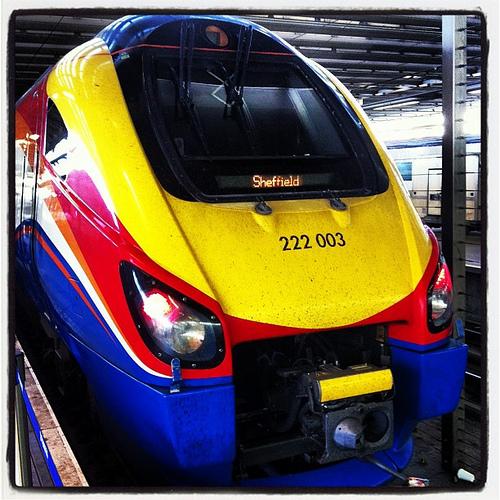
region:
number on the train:
[266, 228, 355, 266]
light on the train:
[143, 315, 208, 369]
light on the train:
[412, 270, 462, 352]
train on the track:
[97, 162, 458, 481]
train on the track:
[8, 22, 430, 421]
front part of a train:
[46, 30, 496, 491]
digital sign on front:
[205, 175, 347, 195]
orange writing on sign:
[240, 167, 310, 191]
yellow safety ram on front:
[300, 370, 402, 468]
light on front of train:
[110, 263, 220, 372]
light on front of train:
[391, 263, 463, 338]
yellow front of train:
[156, 175, 439, 337]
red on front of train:
[61, 178, 140, 285]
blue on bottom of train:
[118, 355, 258, 472]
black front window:
[175, 56, 328, 168]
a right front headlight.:
[109, 255, 226, 377]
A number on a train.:
[269, 225, 354, 262]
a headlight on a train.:
[419, 255, 459, 335]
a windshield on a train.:
[93, 7, 399, 203]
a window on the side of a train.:
[43, 93, 73, 186]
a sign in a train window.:
[250, 156, 314, 193]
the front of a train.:
[297, 331, 417, 498]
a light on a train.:
[107, 254, 241, 376]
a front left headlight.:
[426, 237, 453, 339]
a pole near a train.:
[428, 11, 470, 491]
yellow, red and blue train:
[13, 11, 471, 491]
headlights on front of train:
[125, 268, 467, 371]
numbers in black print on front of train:
[273, 226, 353, 261]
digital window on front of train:
[224, 171, 335, 193]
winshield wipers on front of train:
[171, 14, 271, 136]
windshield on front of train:
[151, 64, 358, 194]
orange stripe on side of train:
[14, 112, 141, 352]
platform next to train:
[14, 344, 89, 496]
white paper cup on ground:
[453, 462, 479, 489]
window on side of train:
[36, 94, 78, 164]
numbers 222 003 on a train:
[256, 220, 351, 252]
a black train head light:
[110, 245, 232, 381]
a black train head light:
[425, 240, 456, 335]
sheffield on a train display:
[241, 167, 320, 197]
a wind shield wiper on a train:
[210, 19, 270, 151]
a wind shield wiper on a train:
[169, 6, 205, 143]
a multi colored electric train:
[15, 25, 465, 484]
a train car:
[381, 128, 487, 228]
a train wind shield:
[151, 46, 376, 196]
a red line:
[97, 20, 322, 71]